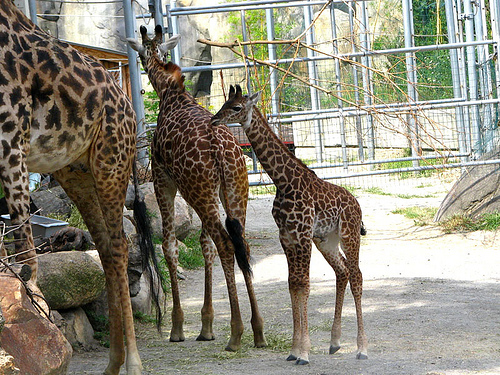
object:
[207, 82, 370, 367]
giraffe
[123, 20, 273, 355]
giraffe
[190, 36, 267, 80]
away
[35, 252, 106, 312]
rocks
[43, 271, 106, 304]
moss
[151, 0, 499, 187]
fence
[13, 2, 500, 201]
enclosure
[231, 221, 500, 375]
ground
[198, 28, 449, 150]
branch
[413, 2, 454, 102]
vegetation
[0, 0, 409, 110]
wall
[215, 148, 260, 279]
tail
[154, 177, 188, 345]
legs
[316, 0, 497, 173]
gate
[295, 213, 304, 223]
spots